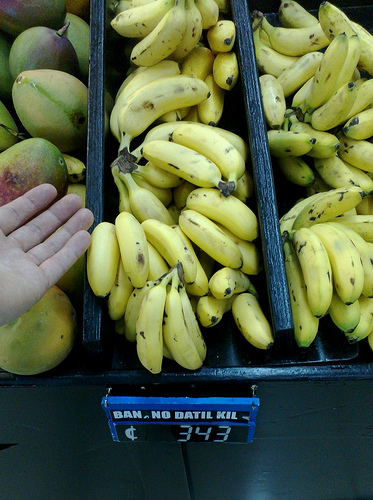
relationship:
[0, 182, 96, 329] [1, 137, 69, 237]
hand by fruit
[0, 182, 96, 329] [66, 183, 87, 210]
hand by fruit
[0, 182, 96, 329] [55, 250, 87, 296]
hand by fruit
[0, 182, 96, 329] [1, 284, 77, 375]
hand by fruit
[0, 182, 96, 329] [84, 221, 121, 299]
hand by fruit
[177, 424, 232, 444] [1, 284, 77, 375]
price of fruit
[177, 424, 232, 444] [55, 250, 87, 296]
price of fruit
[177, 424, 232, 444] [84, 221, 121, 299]
price of fruit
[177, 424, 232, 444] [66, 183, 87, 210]
price of fruit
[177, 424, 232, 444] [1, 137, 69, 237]
price of fruit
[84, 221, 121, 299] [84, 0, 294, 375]
fruit in bin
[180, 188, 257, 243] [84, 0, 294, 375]
banana in bin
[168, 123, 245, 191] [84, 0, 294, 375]
banana in bin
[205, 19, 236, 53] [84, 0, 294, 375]
banana in bin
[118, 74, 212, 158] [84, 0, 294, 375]
banana in bin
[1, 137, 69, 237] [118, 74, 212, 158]
fruit by banana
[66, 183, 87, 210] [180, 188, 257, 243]
fruit by banana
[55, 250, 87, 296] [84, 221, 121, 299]
fruit by fruit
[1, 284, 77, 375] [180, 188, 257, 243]
fruit by banana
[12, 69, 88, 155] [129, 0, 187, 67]
fruit by banana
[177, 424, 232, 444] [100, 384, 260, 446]
price on price sign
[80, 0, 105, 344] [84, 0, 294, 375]
seperator on bin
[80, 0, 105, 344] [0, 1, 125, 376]
seperator on bin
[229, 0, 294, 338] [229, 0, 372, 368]
seperator on bin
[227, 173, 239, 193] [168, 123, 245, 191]
stem of banana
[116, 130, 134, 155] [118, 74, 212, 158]
stem of banana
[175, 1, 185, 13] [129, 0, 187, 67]
stem of banana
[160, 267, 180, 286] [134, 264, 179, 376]
stem of banana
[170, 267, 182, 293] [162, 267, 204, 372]
stem of banana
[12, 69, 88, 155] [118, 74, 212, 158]
fruit near banana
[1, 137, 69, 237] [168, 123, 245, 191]
fruit near banana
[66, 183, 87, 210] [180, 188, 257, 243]
fruit near banana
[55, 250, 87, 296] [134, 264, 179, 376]
fruit near banana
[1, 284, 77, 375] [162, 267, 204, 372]
fruit near banana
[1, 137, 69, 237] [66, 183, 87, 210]
fruit next to fruit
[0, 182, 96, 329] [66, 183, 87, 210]
hand over fruit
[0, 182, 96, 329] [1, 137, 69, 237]
hand over fruit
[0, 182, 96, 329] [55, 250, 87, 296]
hand over fruit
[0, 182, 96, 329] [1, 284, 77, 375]
hand over fruit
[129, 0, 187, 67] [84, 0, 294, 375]
banana in bin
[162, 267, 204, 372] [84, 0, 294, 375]
banana in bin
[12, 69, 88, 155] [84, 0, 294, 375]
fruit on side of bin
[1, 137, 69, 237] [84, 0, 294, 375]
fruit on side of bin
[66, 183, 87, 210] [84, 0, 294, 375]
fruit on side of bin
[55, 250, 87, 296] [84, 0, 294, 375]
fruit on side of bin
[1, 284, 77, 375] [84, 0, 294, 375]
fruit on side of bin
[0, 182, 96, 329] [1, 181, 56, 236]
hand has finger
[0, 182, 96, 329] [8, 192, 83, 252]
hand has finger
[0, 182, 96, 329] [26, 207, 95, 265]
hand has finger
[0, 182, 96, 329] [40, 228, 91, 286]
hand has finger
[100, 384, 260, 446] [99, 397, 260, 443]
price sign has frame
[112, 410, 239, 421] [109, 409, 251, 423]
writing on background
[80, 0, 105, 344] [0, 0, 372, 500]
seperator on fruit stand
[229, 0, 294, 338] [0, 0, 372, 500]
seperator on fruit stand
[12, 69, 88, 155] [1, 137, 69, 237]
fruit together with fruit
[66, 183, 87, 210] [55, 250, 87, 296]
fruit together with fruit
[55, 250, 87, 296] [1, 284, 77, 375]
fruit together with fruit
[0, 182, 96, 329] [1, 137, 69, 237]
hand above fruit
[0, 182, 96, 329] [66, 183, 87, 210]
hand above fruit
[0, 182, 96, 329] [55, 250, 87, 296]
hand above fruit